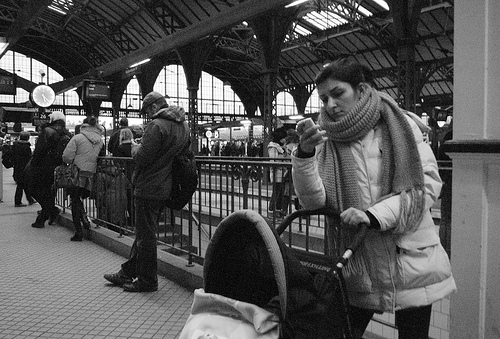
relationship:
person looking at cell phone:
[290, 58, 458, 338] [296, 117, 326, 147]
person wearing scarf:
[290, 64, 447, 338] [316, 94, 437, 276]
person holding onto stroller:
[290, 58, 458, 338] [212, 248, 342, 323]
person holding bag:
[72, 129, 98, 224] [47, 160, 89, 187]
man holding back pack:
[98, 90, 190, 295] [168, 141, 198, 209]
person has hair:
[290, 58, 458, 338] [313, 53, 395, 100]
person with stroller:
[290, 58, 458, 338] [173, 203, 365, 338]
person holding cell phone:
[290, 58, 458, 338] [296, 117, 326, 147]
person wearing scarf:
[290, 58, 458, 338] [317, 92, 427, 225]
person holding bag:
[62, 117, 105, 242] [52, 163, 89, 187]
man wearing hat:
[103, 90, 191, 293] [141, 91, 186, 111]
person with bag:
[62, 117, 105, 242] [52, 163, 89, 187]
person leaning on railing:
[62, 117, 105, 242] [213, 163, 261, 195]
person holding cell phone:
[290, 58, 458, 338] [291, 112, 330, 147]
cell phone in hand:
[293, 117, 326, 142] [292, 119, 332, 155]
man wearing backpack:
[98, 90, 190, 295] [170, 143, 202, 218]